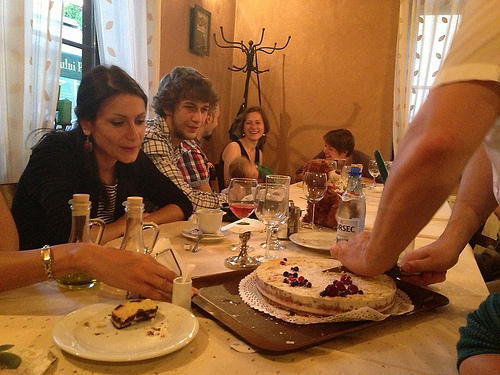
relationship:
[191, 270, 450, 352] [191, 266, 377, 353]
tray has tray part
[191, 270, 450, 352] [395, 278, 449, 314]
tray has tray part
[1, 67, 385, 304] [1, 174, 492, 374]
family sitting around dinner table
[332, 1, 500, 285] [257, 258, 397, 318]
person slicing pie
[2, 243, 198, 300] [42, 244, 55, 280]
hand has watch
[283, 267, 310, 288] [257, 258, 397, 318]
fruit on top of pie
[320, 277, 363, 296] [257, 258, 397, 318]
fruit on top of pie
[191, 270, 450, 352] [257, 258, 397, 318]
tray holding pie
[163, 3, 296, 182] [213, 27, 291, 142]
corner has coat rack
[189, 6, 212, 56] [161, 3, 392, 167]
picture hanging on wall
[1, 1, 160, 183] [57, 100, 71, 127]
window has candle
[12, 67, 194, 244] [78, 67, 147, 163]
woman has head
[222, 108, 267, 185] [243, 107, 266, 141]
woman has head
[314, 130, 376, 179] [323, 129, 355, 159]
woman has head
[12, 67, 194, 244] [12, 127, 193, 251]
woman wearing shirt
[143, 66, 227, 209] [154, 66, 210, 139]
man has head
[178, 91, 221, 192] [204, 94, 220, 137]
man has head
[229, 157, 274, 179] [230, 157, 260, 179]
baby has head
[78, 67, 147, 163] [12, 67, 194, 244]
head on top of woman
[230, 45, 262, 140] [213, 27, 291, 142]
purse hanging on coat rack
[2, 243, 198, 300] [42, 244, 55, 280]
hand wearing watch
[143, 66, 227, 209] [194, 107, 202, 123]
man has nose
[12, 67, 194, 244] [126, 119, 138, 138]
woman has nose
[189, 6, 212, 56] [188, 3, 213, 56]
picture in frame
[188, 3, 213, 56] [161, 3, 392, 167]
frame hanging on wall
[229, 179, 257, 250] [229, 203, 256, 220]
wine glass holding wine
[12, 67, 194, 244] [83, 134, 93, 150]
woman wearing earring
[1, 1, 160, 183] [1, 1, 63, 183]
window has curtain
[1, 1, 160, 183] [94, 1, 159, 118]
window has curtain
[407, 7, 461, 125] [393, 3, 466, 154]
window has curtain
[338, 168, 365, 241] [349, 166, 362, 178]
bottled water has bottle cap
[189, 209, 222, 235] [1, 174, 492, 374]
cup on top of dinner table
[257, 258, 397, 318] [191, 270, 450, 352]
pie on top tray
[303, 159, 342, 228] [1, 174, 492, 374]
toy on top of table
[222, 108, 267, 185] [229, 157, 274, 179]
woman holding baby